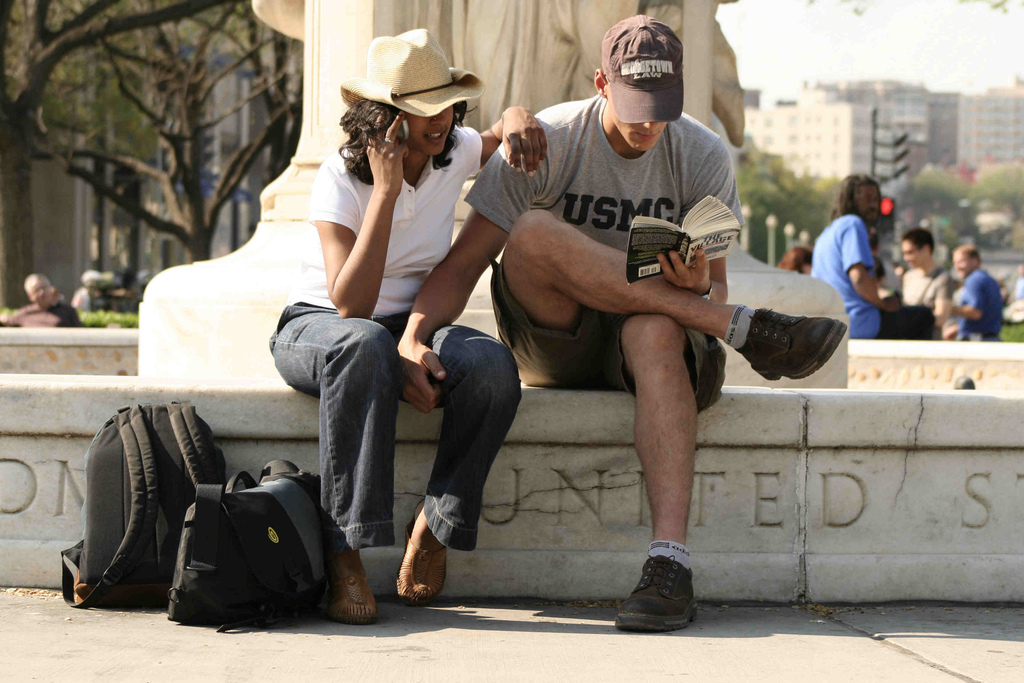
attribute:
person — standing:
[862, 217, 893, 274]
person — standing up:
[769, 229, 809, 277]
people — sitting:
[279, 16, 848, 650]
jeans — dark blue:
[270, 297, 525, 570]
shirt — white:
[309, 122, 502, 326]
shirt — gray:
[473, 91, 765, 306]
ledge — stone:
[6, 363, 1022, 472]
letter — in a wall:
[548, 446, 607, 542]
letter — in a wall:
[814, 456, 867, 545]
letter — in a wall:
[945, 459, 993, 540]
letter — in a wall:
[544, 458, 616, 532]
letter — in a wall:
[747, 459, 795, 537]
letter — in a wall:
[552, 461, 611, 528]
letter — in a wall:
[742, 467, 786, 532]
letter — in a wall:
[818, 463, 868, 531]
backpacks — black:
[60, 402, 348, 629]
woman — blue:
[269, 24, 548, 619]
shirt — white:
[295, 122, 483, 315]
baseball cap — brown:
[600, 14, 687, 118]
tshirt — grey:
[460, 94, 742, 255]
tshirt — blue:
[818, 215, 885, 334]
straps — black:
[86, 396, 205, 597]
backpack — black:
[62, 402, 235, 610]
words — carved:
[0, 450, 1024, 530]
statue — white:
[140, 1, 469, 384]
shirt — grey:
[464, 100, 745, 254]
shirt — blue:
[806, 213, 884, 339]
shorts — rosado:
[486, 250, 739, 417]